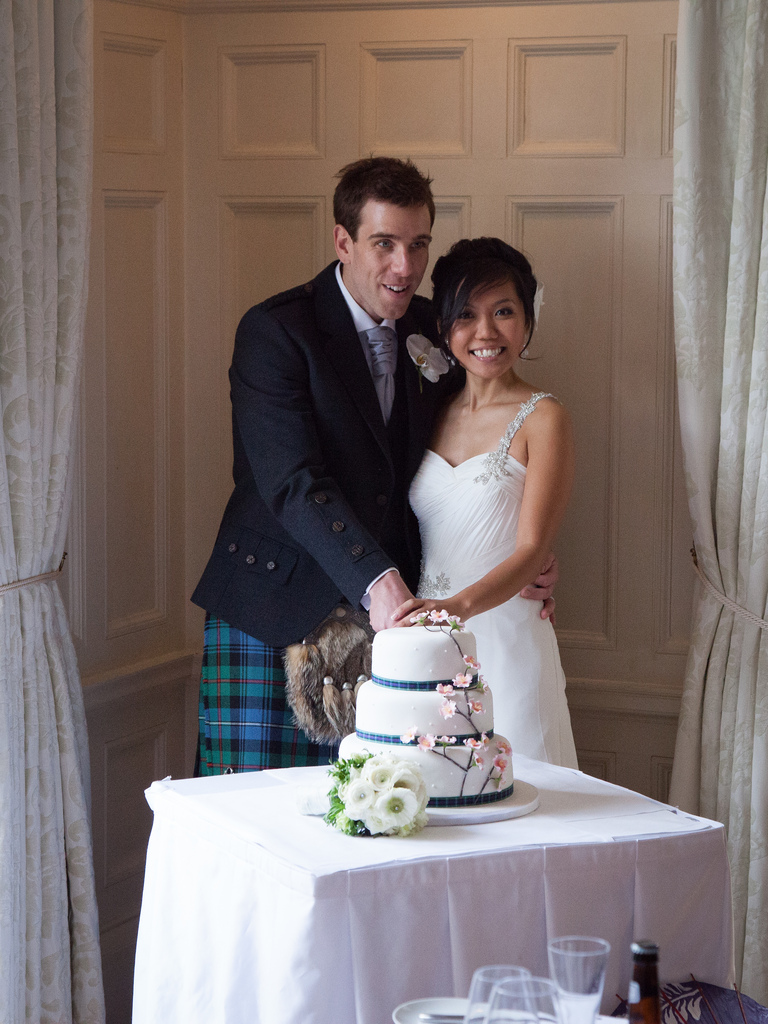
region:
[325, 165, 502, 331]
face of the person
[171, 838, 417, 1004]
a view of cloth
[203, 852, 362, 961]
a view of table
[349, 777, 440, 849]
a view of flower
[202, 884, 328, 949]
light on the cloth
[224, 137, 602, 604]
a cute couple standing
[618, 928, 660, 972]
a view of opener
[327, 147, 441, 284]
man with brown hair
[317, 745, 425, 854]
bouquet of flowers on the table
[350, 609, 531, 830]
wedding cake on the table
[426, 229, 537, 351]
woman with black hair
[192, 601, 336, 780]
man wearing a green kilt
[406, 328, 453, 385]
man wearing a white flower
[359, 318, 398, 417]
man wearing a gray tie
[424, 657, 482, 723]
pink flower on the cake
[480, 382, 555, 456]
gray strap on the shoulder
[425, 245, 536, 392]
the head of a woman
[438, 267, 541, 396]
the face of a woman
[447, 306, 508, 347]
the nose of a woman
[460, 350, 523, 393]
the chin of a woman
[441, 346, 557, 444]
the neck of a woman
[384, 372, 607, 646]
a woman wearing a white dress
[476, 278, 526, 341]
the eye of a woman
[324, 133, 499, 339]
the head of a man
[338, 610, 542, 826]
three-tiered wedding cake on a white tray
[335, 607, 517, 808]
cake has small pink flowers climbing along its front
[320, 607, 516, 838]
bridal bouquet placed in front of cake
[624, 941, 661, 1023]
top of a brown bottle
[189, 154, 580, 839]
couple posing behind cake and bouquet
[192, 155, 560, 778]
groom is wearing a plaid kilt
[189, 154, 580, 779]
groom has his arm around bride's waist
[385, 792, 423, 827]
flower on the cake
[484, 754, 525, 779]
flower on the cake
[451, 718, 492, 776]
flower on the cake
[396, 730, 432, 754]
flower on the cake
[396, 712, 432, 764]
flower on the cake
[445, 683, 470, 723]
flower on the cake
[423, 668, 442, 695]
flower on the cake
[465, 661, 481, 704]
flower on the cake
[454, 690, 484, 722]
flower on the cake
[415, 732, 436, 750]
A flower on a cake.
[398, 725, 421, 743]
A flower on a cake.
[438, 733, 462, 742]
A flower on a cake.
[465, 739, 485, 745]
A flower on a cake.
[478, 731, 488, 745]
A flower on a cake.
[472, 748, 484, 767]
A flower on a cake.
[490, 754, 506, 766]
A flower on a cake.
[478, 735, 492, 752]
A flower on a cake.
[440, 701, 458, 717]
A flower on a cake.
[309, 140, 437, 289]
man has brown hair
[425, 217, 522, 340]
woman has black hair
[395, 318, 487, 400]
man has white flower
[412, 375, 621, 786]
woman has white dress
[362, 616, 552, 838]
blue and white cake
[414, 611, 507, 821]
pink flowers on cake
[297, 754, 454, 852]
green leaves with white flowers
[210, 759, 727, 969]
white table under cake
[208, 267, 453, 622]
man has blue jacket